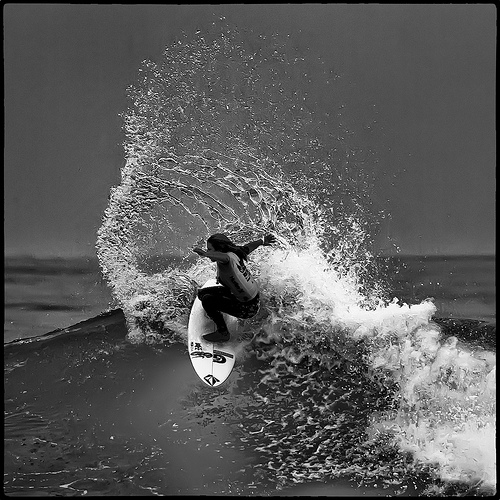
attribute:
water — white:
[204, 175, 464, 447]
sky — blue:
[1, 2, 496, 259]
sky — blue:
[10, 8, 473, 253]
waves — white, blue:
[323, 387, 385, 415]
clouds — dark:
[380, 64, 497, 185]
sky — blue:
[308, 1, 497, 211]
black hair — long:
[205, 232, 249, 262]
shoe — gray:
[202, 327, 231, 342]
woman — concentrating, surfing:
[168, 228, 296, 346]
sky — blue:
[331, 40, 451, 104]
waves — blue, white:
[28, 299, 323, 473]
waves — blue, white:
[4, 205, 495, 487]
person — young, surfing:
[193, 234, 269, 342]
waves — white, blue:
[95, 270, 441, 410]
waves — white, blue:
[47, 306, 200, 411]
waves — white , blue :
[49, 282, 168, 342]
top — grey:
[217, 247, 266, 305]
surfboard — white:
[187, 278, 237, 386]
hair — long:
[216, 238, 233, 250]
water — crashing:
[176, 380, 319, 437]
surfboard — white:
[183, 262, 243, 392]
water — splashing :
[34, 357, 176, 461]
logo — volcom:
[200, 369, 223, 388]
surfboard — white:
[187, 270, 239, 389]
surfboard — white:
[186, 270, 238, 410]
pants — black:
[194, 282, 261, 345]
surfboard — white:
[186, 277, 241, 389]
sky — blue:
[393, 70, 452, 144]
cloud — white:
[399, 139, 481, 225]